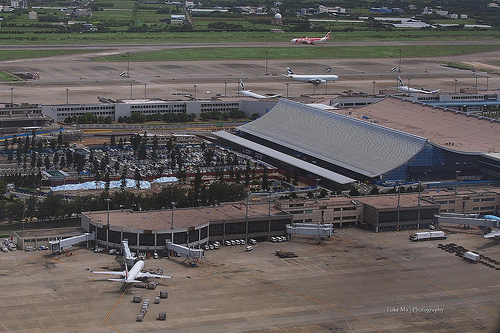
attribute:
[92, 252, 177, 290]
airplane — parked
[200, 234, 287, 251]
carts — white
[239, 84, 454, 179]
roof — slanted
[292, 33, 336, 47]
plane — white, red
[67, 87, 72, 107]
light — tall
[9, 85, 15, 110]
light — tall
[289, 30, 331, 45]
plane — red, white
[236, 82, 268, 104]
plane — white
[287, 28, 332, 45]
plane — white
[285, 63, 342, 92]
plane — white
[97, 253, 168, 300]
plane — white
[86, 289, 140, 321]
line — yellow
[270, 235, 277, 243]
cars — white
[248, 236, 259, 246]
cars — white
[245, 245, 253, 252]
cars — white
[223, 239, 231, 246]
cars — white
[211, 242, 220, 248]
cars — white